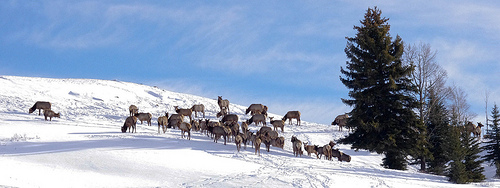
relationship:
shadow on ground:
[6, 74, 474, 185] [2, 80, 474, 185]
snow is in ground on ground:
[28, 126, 130, 186] [2, 80, 474, 185]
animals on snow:
[302, 140, 351, 162] [2, 74, 498, 185]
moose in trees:
[468, 120, 482, 136] [339, 6, 499, 186]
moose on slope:
[217, 95, 229, 113] [0, 74, 498, 184]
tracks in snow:
[2, 73, 498, 185] [2, 74, 498, 185]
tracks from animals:
[2, 73, 498, 185] [302, 140, 351, 162]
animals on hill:
[302, 140, 351, 162] [0, 74, 500, 184]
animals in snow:
[302, 140, 351, 162] [2, 74, 498, 185]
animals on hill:
[302, 140, 351, 162] [0, 73, 499, 188]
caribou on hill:
[28, 95, 484, 164] [0, 74, 500, 184]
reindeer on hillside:
[29, 95, 483, 163] [0, 74, 500, 184]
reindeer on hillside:
[31, 100, 51, 116] [0, 74, 500, 184]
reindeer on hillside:
[120, 116, 138, 134] [0, 74, 500, 184]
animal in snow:
[177, 120, 191, 140] [2, 74, 498, 185]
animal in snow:
[215, 94, 229, 113] [2, 74, 498, 185]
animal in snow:
[284, 110, 301, 124] [2, 74, 498, 185]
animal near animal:
[29, 100, 51, 120] [43, 109, 61, 120]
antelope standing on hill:
[216, 95, 230, 115] [0, 74, 500, 184]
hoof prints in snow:
[211, 162, 341, 185] [2, 74, 498, 185]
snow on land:
[0, 75, 500, 187] [1, 78, 482, 185]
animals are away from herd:
[25, 94, 65, 134] [120, 85, 351, 164]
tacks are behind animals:
[216, 149, 370, 185] [122, 78, 347, 159]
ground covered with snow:
[2, 80, 474, 185] [0, 75, 500, 187]